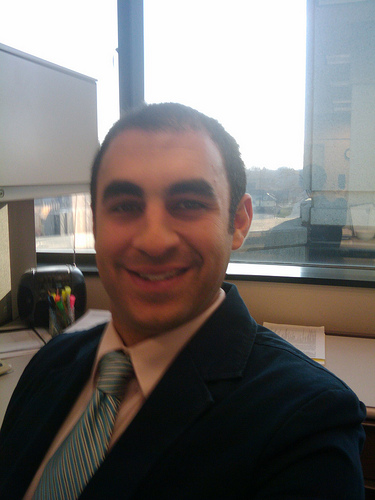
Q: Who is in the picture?
A: A man.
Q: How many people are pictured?
A: One.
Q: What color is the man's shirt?
A: Pink.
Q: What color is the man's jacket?
A: Black.